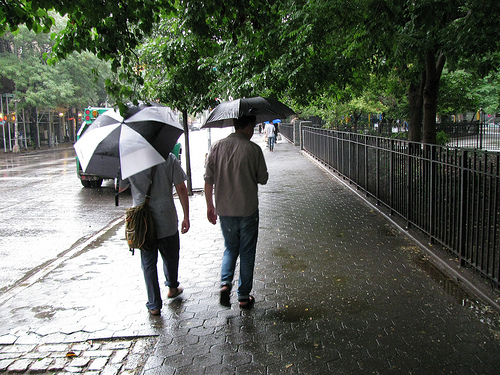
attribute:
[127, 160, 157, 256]
bag — tan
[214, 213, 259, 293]
jeans — pair